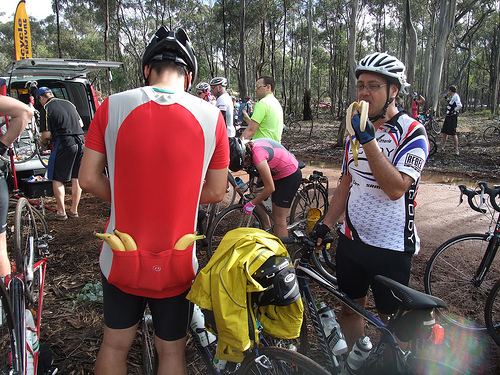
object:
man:
[74, 23, 234, 375]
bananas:
[112, 227, 138, 252]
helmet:
[144, 27, 197, 81]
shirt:
[81, 87, 232, 300]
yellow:
[230, 275, 238, 288]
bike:
[272, 234, 470, 375]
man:
[306, 50, 432, 373]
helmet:
[356, 51, 411, 99]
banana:
[341, 100, 370, 168]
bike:
[0, 196, 57, 375]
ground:
[0, 120, 500, 375]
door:
[3, 56, 123, 80]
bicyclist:
[68, 25, 232, 375]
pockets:
[136, 248, 172, 291]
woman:
[228, 136, 305, 246]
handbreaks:
[457, 182, 468, 206]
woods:
[0, 0, 500, 125]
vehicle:
[12, 57, 95, 187]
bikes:
[205, 169, 331, 263]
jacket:
[182, 225, 305, 366]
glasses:
[355, 81, 385, 91]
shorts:
[99, 274, 190, 342]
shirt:
[248, 92, 287, 143]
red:
[36, 261, 41, 263]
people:
[235, 73, 284, 145]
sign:
[14, 0, 32, 60]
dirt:
[427, 200, 450, 228]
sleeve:
[207, 110, 232, 172]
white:
[387, 56, 393, 60]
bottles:
[315, 300, 349, 357]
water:
[314, 299, 348, 356]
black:
[412, 292, 428, 304]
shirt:
[252, 137, 299, 179]